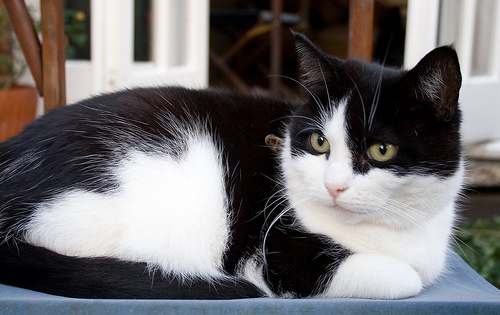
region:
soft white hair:
[394, 164, 466, 286]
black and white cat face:
[283, 78, 465, 235]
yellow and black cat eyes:
[299, 119, 411, 176]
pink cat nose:
[314, 172, 373, 221]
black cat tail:
[6, 157, 272, 307]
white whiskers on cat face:
[244, 156, 450, 252]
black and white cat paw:
[259, 186, 428, 308]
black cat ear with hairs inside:
[396, 6, 490, 108]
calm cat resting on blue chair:
[131, 49, 471, 298]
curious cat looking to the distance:
[235, 46, 474, 308]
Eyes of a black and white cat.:
[306, 128, 399, 163]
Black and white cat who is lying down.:
[2, 26, 462, 301]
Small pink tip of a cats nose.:
[320, 180, 349, 199]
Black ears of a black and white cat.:
[288, 26, 462, 113]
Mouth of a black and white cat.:
[320, 200, 365, 216]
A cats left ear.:
[411, 39, 462, 104]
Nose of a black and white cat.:
[324, 143, 351, 196]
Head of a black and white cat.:
[280, 26, 464, 221]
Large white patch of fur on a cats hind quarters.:
[25, 125, 231, 282]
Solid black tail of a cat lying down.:
[1, 237, 269, 299]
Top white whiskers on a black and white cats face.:
[263, 41, 398, 150]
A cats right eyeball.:
[306, 129, 332, 155]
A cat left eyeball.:
[364, 137, 401, 163]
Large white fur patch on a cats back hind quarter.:
[13, 128, 229, 278]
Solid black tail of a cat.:
[1, 238, 267, 300]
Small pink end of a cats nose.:
[320, 180, 349, 197]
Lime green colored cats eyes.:
[306, 125, 398, 162]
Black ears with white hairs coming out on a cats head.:
[288, 27, 461, 108]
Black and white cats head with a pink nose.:
[279, 27, 463, 226]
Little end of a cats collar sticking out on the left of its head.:
[261, 131, 288, 155]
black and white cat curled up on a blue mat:
[10, 22, 497, 300]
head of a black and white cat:
[263, 9, 475, 244]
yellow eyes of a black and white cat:
[273, 118, 429, 173]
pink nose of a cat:
[307, 172, 369, 209]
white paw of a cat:
[332, 233, 428, 312]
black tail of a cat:
[3, 221, 274, 302]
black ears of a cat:
[274, 33, 471, 99]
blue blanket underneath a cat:
[0, 264, 497, 313]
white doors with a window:
[86, 1, 228, 93]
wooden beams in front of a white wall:
[6, 6, 91, 97]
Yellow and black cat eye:
[302, 126, 332, 158]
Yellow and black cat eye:
[366, 136, 398, 163]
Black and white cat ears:
[278, 17, 464, 112]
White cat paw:
[308, 239, 430, 305]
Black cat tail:
[13, 235, 256, 307]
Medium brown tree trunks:
[11, 4, 71, 109]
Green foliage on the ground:
[452, 217, 498, 288]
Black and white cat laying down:
[0, 48, 484, 303]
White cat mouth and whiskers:
[267, 172, 455, 262]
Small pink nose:
[322, 180, 347, 200]